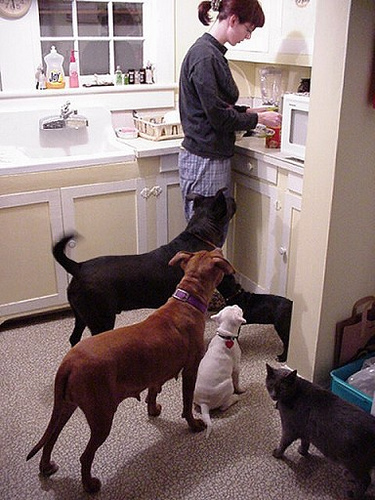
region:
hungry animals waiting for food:
[81, 98, 336, 474]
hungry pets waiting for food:
[64, 102, 330, 437]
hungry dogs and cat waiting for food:
[81, 101, 333, 430]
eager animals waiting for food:
[39, 103, 324, 433]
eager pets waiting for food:
[49, 102, 338, 435]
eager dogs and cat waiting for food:
[55, 53, 327, 430]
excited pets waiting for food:
[60, 120, 324, 449]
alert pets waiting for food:
[75, 64, 325, 427]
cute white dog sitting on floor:
[189, 292, 246, 433]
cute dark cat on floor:
[234, 357, 371, 475]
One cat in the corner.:
[250, 355, 372, 490]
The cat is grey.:
[253, 360, 374, 495]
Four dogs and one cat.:
[38, 188, 373, 492]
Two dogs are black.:
[29, 169, 309, 367]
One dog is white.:
[175, 294, 259, 445]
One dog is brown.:
[12, 241, 241, 495]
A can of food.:
[252, 102, 288, 165]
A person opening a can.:
[170, 0, 289, 313]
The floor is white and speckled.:
[165, 444, 262, 495]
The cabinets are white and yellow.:
[82, 177, 154, 243]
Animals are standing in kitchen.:
[69, 225, 332, 491]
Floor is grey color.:
[120, 439, 245, 492]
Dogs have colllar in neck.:
[168, 225, 252, 352]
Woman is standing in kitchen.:
[181, 10, 248, 230]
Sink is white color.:
[12, 106, 132, 172]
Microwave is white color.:
[267, 95, 322, 163]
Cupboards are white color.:
[270, 8, 312, 54]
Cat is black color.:
[270, 363, 369, 465]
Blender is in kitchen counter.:
[256, 67, 290, 129]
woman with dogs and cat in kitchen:
[119, 32, 329, 465]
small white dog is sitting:
[193, 301, 248, 409]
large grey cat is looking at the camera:
[251, 349, 361, 487]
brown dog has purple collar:
[167, 270, 204, 334]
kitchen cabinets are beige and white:
[12, 150, 168, 226]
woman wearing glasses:
[195, 15, 270, 34]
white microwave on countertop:
[281, 86, 308, 165]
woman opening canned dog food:
[256, 120, 282, 155]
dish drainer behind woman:
[127, 105, 187, 141]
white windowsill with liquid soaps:
[23, 50, 125, 92]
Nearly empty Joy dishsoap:
[37, 40, 62, 87]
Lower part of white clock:
[0, 0, 32, 17]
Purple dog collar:
[169, 280, 206, 311]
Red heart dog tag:
[218, 336, 233, 346]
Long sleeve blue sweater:
[175, 38, 251, 152]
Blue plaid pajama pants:
[168, 137, 234, 238]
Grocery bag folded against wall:
[326, 273, 371, 366]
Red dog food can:
[257, 121, 278, 147]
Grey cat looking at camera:
[263, 361, 372, 489]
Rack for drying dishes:
[126, 107, 189, 142]